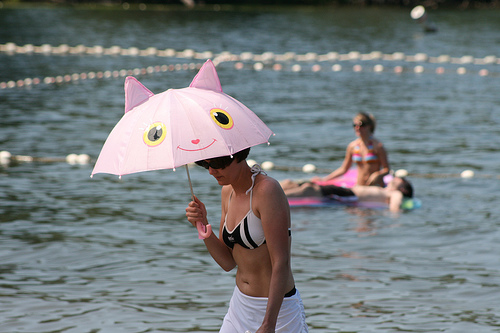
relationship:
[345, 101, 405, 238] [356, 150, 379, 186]
girl in bikini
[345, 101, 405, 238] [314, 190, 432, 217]
girl with guy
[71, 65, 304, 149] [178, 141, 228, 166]
umbrella with smile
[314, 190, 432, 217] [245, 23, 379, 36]
guy floating in water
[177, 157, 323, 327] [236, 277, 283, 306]
woman showing belly button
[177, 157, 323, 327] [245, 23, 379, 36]
woman in water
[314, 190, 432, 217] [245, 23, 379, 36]
guy in water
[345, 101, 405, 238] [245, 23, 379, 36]
girl in water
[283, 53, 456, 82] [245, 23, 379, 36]
buoys in water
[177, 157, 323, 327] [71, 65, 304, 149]
woman walking with umbrella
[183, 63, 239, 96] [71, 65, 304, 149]
right ear on umbrella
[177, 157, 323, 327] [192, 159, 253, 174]
woman in sunglasses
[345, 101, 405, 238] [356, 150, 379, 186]
girl wearing bikini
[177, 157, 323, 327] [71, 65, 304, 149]
woman with umbrella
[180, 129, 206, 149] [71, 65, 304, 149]
nose of umbrella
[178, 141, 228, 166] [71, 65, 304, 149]
smile on umbrella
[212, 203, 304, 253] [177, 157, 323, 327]
bikini top on woman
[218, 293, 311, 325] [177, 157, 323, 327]
shorts on woman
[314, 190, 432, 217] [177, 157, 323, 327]
guy behind woman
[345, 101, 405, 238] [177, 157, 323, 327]
girl behind woman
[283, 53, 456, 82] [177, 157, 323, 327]
buoys behind woman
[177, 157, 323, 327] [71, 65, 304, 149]
woman holding umbrella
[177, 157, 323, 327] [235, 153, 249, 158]
woman has dark hair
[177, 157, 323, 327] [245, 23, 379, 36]
woman by water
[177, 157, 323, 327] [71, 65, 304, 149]
woman carrying umbrella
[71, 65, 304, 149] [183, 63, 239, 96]
umbrella with right ear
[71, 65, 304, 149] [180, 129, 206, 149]
umbrella with nose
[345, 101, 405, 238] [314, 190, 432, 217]
girl by guy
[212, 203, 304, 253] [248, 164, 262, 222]
bikini top with white strings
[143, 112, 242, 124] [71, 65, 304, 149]
eyes on umbrella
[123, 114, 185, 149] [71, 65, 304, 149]
left eye on umbrella